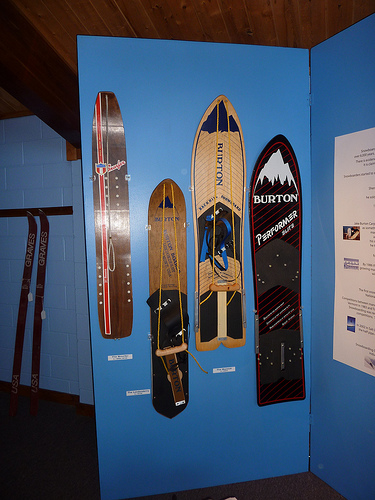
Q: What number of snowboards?
A: Four.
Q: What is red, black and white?
A: Snowboard.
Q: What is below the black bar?
A: Skis.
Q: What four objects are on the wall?
A: Snowboards.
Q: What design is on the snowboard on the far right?
A: Mountain.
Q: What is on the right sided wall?
A: Poster.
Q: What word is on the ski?
A: Graves.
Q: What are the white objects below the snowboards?
A: White stickers.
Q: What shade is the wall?
A: Blue.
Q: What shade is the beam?
A: Black.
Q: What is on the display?
A: Snowboards.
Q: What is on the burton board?
A: A mountain.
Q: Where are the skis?
A: Against the wall.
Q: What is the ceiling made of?
A: Wood.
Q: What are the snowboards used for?
A: Snowboarding.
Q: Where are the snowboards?
A: On the display.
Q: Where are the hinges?
A: On the display.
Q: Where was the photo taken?
A: Inside a room.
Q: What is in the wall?
A: Rocket.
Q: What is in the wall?
A: Snowboad.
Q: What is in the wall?
A: Skateboard.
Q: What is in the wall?
A: Boards.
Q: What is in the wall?
A: Art.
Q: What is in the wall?
A: Display.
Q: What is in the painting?
A: Board.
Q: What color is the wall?
A: Blue.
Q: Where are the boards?
A: On the wall.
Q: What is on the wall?
A: Boards.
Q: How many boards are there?
A: Four.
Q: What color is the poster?
A: White.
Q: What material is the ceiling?
A: Wood.